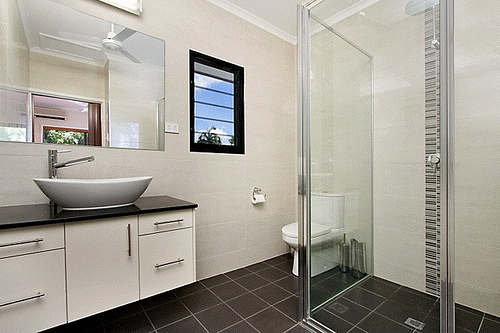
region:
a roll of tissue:
[252, 193, 262, 205]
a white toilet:
[280, 185, 355, 277]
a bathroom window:
[192, 54, 240, 146]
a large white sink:
[33, 171, 157, 211]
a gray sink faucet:
[41, 144, 98, 176]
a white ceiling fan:
[37, 22, 147, 64]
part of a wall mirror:
[0, 0, 172, 160]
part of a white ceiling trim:
[208, 0, 298, 47]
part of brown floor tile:
[90, 250, 300, 330]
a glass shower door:
[302, 0, 499, 332]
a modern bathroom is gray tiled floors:
[3, 3, 497, 328]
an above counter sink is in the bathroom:
[33, 171, 153, 211]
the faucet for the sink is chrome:
[44, 142, 98, 221]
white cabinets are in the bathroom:
[2, 212, 196, 330]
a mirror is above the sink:
[0, 0, 167, 157]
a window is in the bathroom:
[183, 45, 248, 155]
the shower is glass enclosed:
[296, 5, 497, 331]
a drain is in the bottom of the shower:
[398, 313, 428, 332]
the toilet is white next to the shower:
[281, 189, 347, 284]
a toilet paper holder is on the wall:
[247, 185, 269, 208]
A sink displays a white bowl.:
[44, 173, 156, 206]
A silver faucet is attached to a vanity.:
[33, 145, 100, 180]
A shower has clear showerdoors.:
[303, 6, 455, 331]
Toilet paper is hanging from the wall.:
[251, 183, 271, 228]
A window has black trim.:
[188, 53, 245, 157]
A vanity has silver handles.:
[13, 212, 198, 284]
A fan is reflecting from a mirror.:
[43, 20, 157, 71]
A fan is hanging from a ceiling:
[47, 25, 187, 55]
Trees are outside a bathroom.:
[198, 117, 228, 162]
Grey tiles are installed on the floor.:
[208, 273, 311, 330]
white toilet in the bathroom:
[286, 192, 346, 279]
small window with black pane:
[190, 53, 247, 153]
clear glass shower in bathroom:
[300, 5, 499, 331]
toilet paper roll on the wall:
[251, 190, 267, 207]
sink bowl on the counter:
[36, 175, 151, 207]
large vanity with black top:
[2, 205, 195, 332]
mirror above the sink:
[8, 2, 165, 150]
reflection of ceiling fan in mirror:
[67, 28, 141, 64]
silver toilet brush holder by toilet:
[337, 233, 350, 277]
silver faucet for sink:
[49, 147, 93, 204]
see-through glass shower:
[292, 2, 474, 328]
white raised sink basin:
[28, 151, 151, 211]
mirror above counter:
[0, 0, 180, 165]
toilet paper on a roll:
[246, 177, 272, 205]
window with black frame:
[185, 37, 251, 163]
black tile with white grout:
[0, 233, 498, 329]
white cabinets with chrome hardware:
[0, 195, 200, 327]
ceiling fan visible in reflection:
[51, 20, 142, 67]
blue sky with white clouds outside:
[185, 48, 246, 153]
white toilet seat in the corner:
[282, 187, 345, 283]